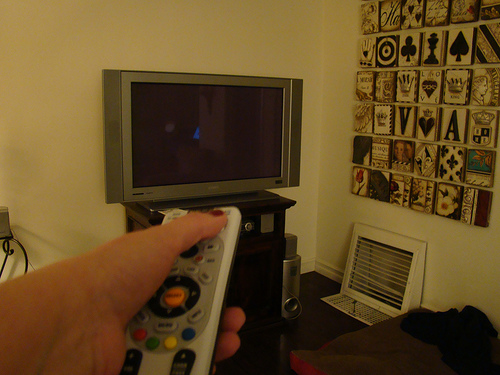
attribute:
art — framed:
[349, 165, 369, 197]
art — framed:
[388, 136, 416, 173]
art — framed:
[436, 144, 466, 181]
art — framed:
[434, 180, 462, 220]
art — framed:
[374, 34, 397, 67]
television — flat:
[91, 63, 312, 210]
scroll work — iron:
[0, 238, 27, 280]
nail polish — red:
[205, 201, 229, 231]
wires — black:
[1, 236, 28, 282]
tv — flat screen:
[109, 75, 299, 184]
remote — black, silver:
[122, 206, 239, 373]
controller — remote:
[97, 196, 253, 373]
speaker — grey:
[280, 256, 305, 323]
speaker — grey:
[287, 230, 298, 255]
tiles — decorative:
[351, 70, 373, 99]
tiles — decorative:
[413, 105, 439, 142]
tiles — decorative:
[430, 182, 462, 219]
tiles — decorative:
[417, 27, 447, 68]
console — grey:
[274, 222, 324, 351]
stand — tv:
[123, 189, 297, 373]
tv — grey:
[102, 66, 302, 213]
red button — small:
[129, 326, 148, 340]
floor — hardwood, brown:
[278, 269, 370, 354]